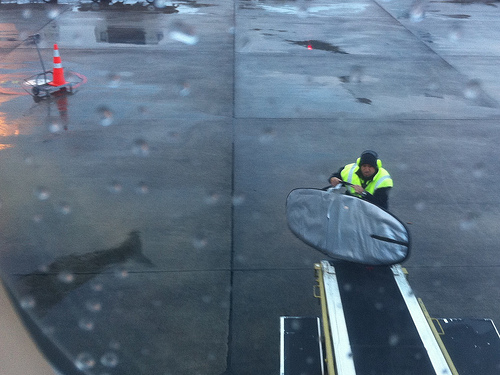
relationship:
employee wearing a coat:
[327, 149, 394, 211] [339, 157, 394, 199]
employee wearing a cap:
[328, 149, 394, 208] [358, 150, 378, 172]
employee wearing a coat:
[328, 149, 394, 208] [327, 160, 391, 209]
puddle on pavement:
[285, 39, 349, 56] [215, 14, 452, 149]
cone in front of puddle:
[40, 36, 74, 92] [49, 14, 199, 63]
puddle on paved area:
[294, 37, 346, 56] [0, 0, 500, 375]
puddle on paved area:
[90, 20, 180, 48] [0, 0, 500, 375]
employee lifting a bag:
[328, 149, 394, 208] [285, 179, 415, 269]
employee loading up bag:
[328, 149, 394, 208] [283, 181, 412, 267]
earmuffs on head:
[354, 157, 380, 169] [353, 147, 383, 183]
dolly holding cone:
[29, 71, 79, 104] [45, 42, 70, 87]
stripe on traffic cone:
[52, 48, 60, 55] [47, 42, 69, 88]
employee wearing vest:
[328, 149, 394, 208] [340, 165, 388, 197]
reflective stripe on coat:
[345, 161, 356, 183] [339, 157, 394, 199]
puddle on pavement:
[0, 0, 206, 49] [230, 11, 454, 139]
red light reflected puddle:
[302, 40, 314, 50] [292, 38, 346, 57]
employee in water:
[328, 149, 394, 208] [52, 132, 497, 354]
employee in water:
[328, 149, 394, 208] [64, 64, 498, 285]